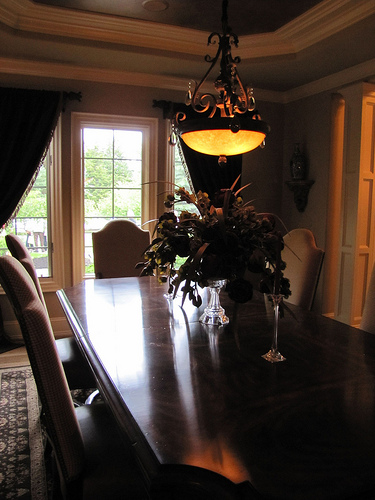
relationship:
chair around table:
[0, 245, 133, 480] [52, 266, 373, 498]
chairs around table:
[0, 233, 102, 456] [52, 266, 373, 498]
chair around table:
[92, 220, 151, 278] [52, 266, 373, 498]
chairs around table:
[263, 225, 325, 310] [52, 266, 373, 498]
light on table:
[173, 436, 251, 486] [52, 266, 373, 498]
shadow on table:
[137, 301, 190, 437] [52, 266, 373, 498]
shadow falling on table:
[137, 301, 190, 437] [52, 266, 373, 498]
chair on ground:
[92, 220, 150, 278] [1, 327, 372, 498]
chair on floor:
[92, 220, 150, 278] [1, 339, 373, 497]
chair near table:
[92, 220, 151, 278] [52, 266, 373, 498]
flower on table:
[137, 178, 290, 363] [52, 266, 373, 498]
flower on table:
[137, 178, 296, 360] [52, 266, 373, 498]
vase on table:
[199, 273, 232, 326] [52, 266, 373, 498]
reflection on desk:
[85, 270, 220, 446] [63, 272, 374, 497]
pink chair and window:
[62, 224, 179, 283] [70, 113, 157, 304]